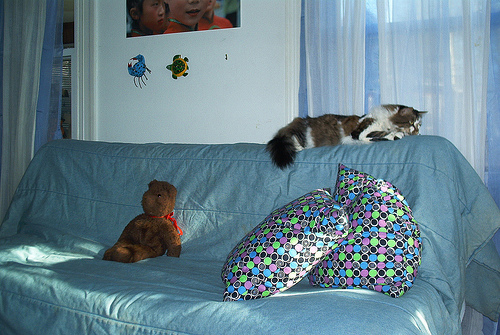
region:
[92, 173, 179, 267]
Teddy bear is sitting on couch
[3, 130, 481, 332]
Blue blanket covering the couch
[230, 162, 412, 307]
Two colorful pillows on the couch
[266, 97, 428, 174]
Cat lying on back of couch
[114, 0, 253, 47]
Picture hanging on the wall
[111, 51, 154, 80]
Picture of blue crab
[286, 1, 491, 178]
Sheer white curtains on window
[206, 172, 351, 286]
Pillow is falling down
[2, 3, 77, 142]
Blue curtain behind white curtain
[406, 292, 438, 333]
Sun light on couch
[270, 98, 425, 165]
cat laying on a couch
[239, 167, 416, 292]
colorful circular designed pillows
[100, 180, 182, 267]
teddy bear wearing a red ribbon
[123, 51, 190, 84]
turtle and crab on the wall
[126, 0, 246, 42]
poster of kids faces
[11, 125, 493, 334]
couch with a blue cover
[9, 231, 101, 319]
sunlight shining on the couch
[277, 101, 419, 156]
black grey and white cat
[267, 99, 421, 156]
cat with very long hair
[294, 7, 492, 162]
white and blue curtains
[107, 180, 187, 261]
a brown teddy bear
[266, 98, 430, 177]
a large black and white car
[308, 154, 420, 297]
a large colorful pillow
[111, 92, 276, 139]
part of a painted white wall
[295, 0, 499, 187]
part of a blue and white curtain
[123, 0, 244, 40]
part of a picture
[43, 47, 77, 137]
part of a window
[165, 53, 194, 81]
a small wall figure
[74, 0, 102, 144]
part of a white window trim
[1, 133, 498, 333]
a long blue blanket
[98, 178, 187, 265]
Brown teddy bear on a couchc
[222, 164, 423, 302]
Patterned pillows on a couch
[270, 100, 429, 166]
A cat on top of a couch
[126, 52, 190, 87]
Decorations on a white wall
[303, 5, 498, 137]
Drapes hanging over a window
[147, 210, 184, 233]
Red ribbon of a stuffed animal toy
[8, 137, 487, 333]
A sofa covered with a blue blanket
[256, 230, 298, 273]
Pattern on a pillow's case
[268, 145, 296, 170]
Tip of a cat's tail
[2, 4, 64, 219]
Drapes hang over a window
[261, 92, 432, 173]
A cat resting on a couch